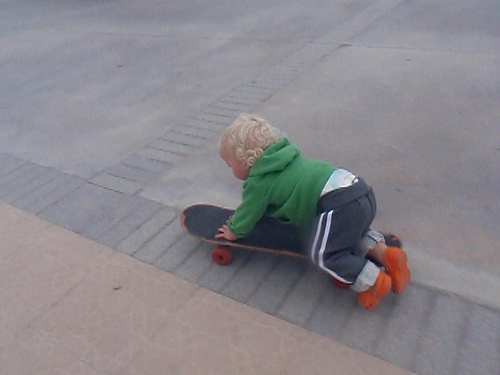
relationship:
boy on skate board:
[209, 108, 414, 318] [174, 199, 309, 271]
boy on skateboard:
[209, 108, 414, 318] [177, 196, 408, 277]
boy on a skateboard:
[213, 112, 411, 309] [179, 204, 289, 254]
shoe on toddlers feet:
[387, 249, 410, 301] [354, 247, 411, 308]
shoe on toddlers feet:
[358, 275, 393, 310] [354, 247, 411, 308]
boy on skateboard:
[213, 112, 411, 309] [177, 196, 408, 277]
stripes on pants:
[310, 206, 354, 286] [309, 182, 388, 282]